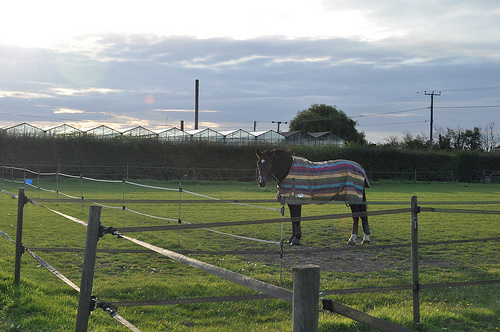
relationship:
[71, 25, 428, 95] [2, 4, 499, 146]
clouds in sky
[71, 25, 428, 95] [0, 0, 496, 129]
clouds in sky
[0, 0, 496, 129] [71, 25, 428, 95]
sky has clouds